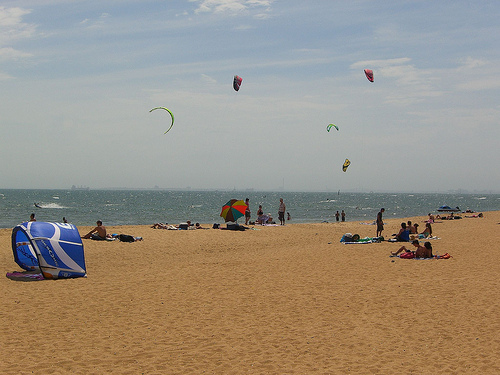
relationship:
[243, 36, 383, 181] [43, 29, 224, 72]
kites in air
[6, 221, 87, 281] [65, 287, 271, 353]
arch on ground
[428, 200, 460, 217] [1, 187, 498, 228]
boat in ocean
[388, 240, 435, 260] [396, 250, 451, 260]
couple on red towel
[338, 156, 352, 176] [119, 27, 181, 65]
kite in air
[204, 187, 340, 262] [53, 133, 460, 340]
people on beach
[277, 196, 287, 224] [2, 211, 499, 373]
people on beach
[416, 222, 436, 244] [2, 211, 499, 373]
person on beach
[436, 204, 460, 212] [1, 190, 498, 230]
boat in water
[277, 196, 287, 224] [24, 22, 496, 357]
people lying on beach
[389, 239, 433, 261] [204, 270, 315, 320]
couple laying on sand